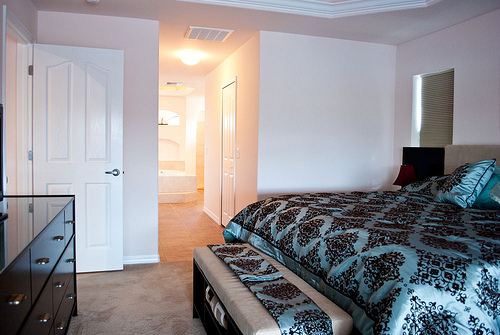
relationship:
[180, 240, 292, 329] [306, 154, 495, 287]
bench in front of bed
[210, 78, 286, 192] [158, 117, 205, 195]
closet in bathroom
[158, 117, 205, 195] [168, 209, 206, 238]
bathroom has floor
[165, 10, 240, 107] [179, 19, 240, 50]
ceiling has vent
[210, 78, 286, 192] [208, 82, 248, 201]
closet has door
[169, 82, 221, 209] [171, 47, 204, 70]
hallway has light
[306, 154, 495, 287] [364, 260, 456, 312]
bed has bedspread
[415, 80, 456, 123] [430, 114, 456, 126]
window has blinds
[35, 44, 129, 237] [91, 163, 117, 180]
door has handle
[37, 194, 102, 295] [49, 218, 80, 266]
dresser has drawer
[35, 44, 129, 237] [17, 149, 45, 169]
door has hinge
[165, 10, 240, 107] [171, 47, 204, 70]
ceiling has light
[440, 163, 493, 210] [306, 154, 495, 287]
pillow on bed